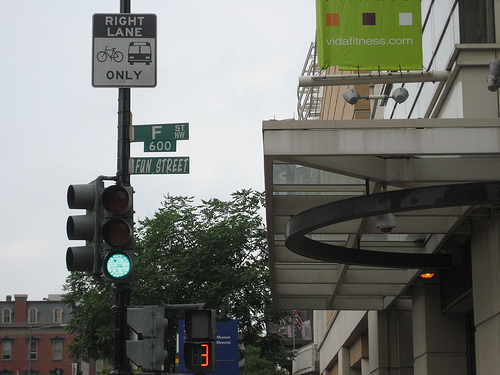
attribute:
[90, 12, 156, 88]
sign — square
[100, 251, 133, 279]
light — green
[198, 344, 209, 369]
three — red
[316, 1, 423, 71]
sign — green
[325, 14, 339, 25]
square — orange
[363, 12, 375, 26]
square — purple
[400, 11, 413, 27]
square — white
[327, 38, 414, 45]
writing — white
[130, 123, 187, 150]
sign — green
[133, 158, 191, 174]
sign — green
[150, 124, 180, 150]
writing — white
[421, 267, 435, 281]
light — on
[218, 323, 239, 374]
sign — blue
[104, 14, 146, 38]
writing — white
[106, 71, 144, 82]
writing — black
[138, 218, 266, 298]
tree — green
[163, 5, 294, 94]
sky — grey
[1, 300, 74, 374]
building — brick